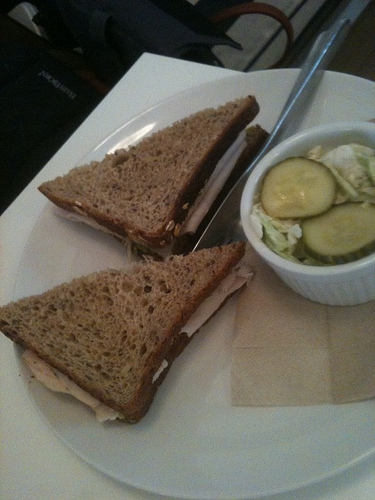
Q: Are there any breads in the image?
A: Yes, there is a bread.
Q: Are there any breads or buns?
A: Yes, there is a bread.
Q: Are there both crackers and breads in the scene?
A: No, there is a bread but no crackers.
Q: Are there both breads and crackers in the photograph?
A: No, there is a bread but no crackers.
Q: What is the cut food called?
A: The food is a bread.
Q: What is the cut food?
A: The food is a bread.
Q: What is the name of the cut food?
A: The food is a bread.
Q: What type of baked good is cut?
A: The baked good is a bread.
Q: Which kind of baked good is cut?
A: The baked good is a bread.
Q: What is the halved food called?
A: The food is a bread.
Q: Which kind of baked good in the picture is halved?
A: The baked good is a bread.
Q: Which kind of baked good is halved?
A: The baked good is a bread.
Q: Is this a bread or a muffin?
A: This is a bread.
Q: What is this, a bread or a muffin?
A: This is a bread.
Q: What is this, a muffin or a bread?
A: This is a bread.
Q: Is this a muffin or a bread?
A: This is a bread.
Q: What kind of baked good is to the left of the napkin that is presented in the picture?
A: The food is a bread.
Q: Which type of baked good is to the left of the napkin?
A: The food is a bread.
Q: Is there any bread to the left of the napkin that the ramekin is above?
A: Yes, there is a bread to the left of the napkin.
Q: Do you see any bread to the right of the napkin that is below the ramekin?
A: No, the bread is to the left of the napkin.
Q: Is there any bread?
A: Yes, there is a bread.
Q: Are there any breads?
A: Yes, there is a bread.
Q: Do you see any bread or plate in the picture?
A: Yes, there is a bread.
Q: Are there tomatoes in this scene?
A: No, there are no tomatoes.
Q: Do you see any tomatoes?
A: No, there are no tomatoes.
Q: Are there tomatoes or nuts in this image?
A: No, there are no tomatoes or nuts.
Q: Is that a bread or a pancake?
A: That is a bread.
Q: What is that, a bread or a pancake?
A: That is a bread.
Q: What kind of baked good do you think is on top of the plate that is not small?
A: The food is a bread.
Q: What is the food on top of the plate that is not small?
A: The food is a bread.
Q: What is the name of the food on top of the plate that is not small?
A: The food is a bread.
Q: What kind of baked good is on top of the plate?
A: The food is a bread.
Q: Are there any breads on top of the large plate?
A: Yes, there is a bread on top of the plate.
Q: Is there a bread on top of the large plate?
A: Yes, there is a bread on top of the plate.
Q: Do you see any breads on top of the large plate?
A: Yes, there is a bread on top of the plate.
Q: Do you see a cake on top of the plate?
A: No, there is a bread on top of the plate.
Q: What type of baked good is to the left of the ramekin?
A: The food is a bread.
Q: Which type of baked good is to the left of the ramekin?
A: The food is a bread.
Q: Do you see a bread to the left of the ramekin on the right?
A: Yes, there is a bread to the left of the ramekin.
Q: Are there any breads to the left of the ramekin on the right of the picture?
A: Yes, there is a bread to the left of the ramekin.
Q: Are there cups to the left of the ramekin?
A: No, there is a bread to the left of the ramekin.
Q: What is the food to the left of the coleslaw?
A: The food is a bread.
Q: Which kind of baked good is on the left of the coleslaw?
A: The food is a bread.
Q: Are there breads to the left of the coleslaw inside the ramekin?
A: Yes, there is a bread to the left of the coleslaw.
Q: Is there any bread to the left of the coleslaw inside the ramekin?
A: Yes, there is a bread to the left of the coleslaw.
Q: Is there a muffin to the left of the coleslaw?
A: No, there is a bread to the left of the coleslaw.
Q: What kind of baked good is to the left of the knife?
A: The food is a bread.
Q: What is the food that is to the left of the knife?
A: The food is a bread.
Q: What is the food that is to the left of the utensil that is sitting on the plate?
A: The food is a bread.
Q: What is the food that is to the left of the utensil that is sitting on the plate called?
A: The food is a bread.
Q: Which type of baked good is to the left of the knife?
A: The food is a bread.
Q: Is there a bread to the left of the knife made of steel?
A: Yes, there is a bread to the left of the knife.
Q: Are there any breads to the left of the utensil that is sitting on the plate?
A: Yes, there is a bread to the left of the knife.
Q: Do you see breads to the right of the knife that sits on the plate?
A: No, the bread is to the left of the knife.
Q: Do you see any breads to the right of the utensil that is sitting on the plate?
A: No, the bread is to the left of the knife.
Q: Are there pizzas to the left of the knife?
A: No, there is a bread to the left of the knife.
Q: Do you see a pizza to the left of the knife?
A: No, there is a bread to the left of the knife.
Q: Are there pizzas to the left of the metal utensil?
A: No, there is a bread to the left of the knife.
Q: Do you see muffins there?
A: No, there are no muffins.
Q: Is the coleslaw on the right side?
A: Yes, the coleslaw is on the right of the image.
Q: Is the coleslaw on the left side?
A: No, the coleslaw is on the right of the image.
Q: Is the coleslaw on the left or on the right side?
A: The coleslaw is on the right of the image.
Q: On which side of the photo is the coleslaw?
A: The coleslaw is on the right of the image.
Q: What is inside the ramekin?
A: The coleslaw is inside the ramekin.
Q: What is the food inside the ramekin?
A: The food is coleslaw.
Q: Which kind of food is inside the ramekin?
A: The food is coleslaw.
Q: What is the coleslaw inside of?
A: The coleslaw is inside the ramekin.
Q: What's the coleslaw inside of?
A: The coleslaw is inside the ramekin.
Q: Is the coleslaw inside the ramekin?
A: Yes, the coleslaw is inside the ramekin.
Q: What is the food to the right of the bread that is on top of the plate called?
A: The food is coleslaw.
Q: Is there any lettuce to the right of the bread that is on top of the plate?
A: No, there is coleslaw to the right of the bread.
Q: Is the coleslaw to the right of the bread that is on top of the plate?
A: Yes, the coleslaw is to the right of the bread.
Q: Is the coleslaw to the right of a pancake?
A: No, the coleslaw is to the right of the bread.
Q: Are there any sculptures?
A: No, there are no sculptures.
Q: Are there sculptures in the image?
A: No, there are no sculptures.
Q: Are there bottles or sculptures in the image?
A: No, there are no sculptures or bottles.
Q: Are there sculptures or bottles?
A: No, there are no sculptures or bottles.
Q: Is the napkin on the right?
A: Yes, the napkin is on the right of the image.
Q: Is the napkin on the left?
A: No, the napkin is on the right of the image.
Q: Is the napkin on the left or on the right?
A: The napkin is on the right of the image.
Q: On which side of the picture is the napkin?
A: The napkin is on the right of the image.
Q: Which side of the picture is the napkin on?
A: The napkin is on the right of the image.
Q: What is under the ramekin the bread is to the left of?
A: The napkin is under the ramekin.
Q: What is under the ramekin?
A: The napkin is under the ramekin.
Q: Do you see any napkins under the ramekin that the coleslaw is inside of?
A: Yes, there is a napkin under the ramekin.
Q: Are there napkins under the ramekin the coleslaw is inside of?
A: Yes, there is a napkin under the ramekin.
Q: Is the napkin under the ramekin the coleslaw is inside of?
A: Yes, the napkin is under the ramekin.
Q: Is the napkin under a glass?
A: No, the napkin is under the ramekin.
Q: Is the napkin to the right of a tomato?
A: No, the napkin is to the right of the bread.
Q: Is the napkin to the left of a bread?
A: No, the napkin is to the right of a bread.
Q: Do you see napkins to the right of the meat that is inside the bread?
A: Yes, there is a napkin to the right of the meat.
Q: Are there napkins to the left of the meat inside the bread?
A: No, the napkin is to the right of the meat.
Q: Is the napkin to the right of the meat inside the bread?
A: Yes, the napkin is to the right of the meat.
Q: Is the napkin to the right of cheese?
A: No, the napkin is to the right of the meat.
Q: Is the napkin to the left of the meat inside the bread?
A: No, the napkin is to the right of the meat.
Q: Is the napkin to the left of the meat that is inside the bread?
A: No, the napkin is to the right of the meat.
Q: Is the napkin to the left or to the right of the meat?
A: The napkin is to the right of the meat.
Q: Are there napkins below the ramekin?
A: Yes, there is a napkin below the ramekin.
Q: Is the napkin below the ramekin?
A: Yes, the napkin is below the ramekin.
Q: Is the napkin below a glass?
A: No, the napkin is below the ramekin.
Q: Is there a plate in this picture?
A: Yes, there is a plate.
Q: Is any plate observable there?
A: Yes, there is a plate.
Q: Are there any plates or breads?
A: Yes, there is a plate.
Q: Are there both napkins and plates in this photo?
A: Yes, there are both a plate and a napkin.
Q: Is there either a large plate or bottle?
A: Yes, there is a large plate.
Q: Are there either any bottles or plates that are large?
A: Yes, the plate is large.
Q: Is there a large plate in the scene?
A: Yes, there is a large plate.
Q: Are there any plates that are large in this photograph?
A: Yes, there is a large plate.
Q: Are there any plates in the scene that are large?
A: Yes, there is a plate that is large.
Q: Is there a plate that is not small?
A: Yes, there is a large plate.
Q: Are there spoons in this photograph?
A: No, there are no spoons.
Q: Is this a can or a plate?
A: This is a plate.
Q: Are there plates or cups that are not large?
A: No, there is a plate but it is large.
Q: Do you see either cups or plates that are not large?
A: No, there is a plate but it is large.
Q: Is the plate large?
A: Yes, the plate is large.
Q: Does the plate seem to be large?
A: Yes, the plate is large.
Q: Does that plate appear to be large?
A: Yes, the plate is large.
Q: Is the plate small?
A: No, the plate is large.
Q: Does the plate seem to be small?
A: No, the plate is large.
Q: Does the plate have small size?
A: No, the plate is large.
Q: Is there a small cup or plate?
A: No, there is a plate but it is large.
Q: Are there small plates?
A: No, there is a plate but it is large.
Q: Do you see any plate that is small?
A: No, there is a plate but it is large.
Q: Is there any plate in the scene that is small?
A: No, there is a plate but it is large.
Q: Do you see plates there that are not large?
A: No, there is a plate but it is large.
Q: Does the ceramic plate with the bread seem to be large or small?
A: The plate is large.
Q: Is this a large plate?
A: Yes, this is a large plate.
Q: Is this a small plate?
A: No, this is a large plate.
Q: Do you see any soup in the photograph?
A: No, there is no soup.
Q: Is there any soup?
A: No, there is no soup.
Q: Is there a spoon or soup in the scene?
A: No, there are no soup or spoons.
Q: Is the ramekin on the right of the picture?
A: Yes, the ramekin is on the right of the image.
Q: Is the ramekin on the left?
A: No, the ramekin is on the right of the image.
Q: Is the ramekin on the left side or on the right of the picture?
A: The ramekin is on the right of the image.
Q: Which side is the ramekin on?
A: The ramekin is on the right of the image.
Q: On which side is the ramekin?
A: The ramekin is on the right of the image.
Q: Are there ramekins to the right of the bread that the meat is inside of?
A: Yes, there is a ramekin to the right of the bread.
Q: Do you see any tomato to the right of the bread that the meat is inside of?
A: No, there is a ramekin to the right of the bread.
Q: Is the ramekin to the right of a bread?
A: Yes, the ramekin is to the right of a bread.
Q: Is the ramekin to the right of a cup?
A: No, the ramekin is to the right of a bread.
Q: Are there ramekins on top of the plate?
A: Yes, there is a ramekin on top of the plate.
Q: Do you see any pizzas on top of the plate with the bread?
A: No, there is a ramekin on top of the plate.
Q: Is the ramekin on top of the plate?
A: Yes, the ramekin is on top of the plate.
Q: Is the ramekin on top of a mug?
A: No, the ramekin is on top of the plate.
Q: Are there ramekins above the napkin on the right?
A: Yes, there is a ramekin above the napkin.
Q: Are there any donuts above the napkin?
A: No, there is a ramekin above the napkin.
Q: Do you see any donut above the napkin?
A: No, there is a ramekin above the napkin.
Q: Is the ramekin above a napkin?
A: Yes, the ramekin is above a napkin.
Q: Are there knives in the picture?
A: Yes, there is a knife.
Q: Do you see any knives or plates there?
A: Yes, there is a knife.